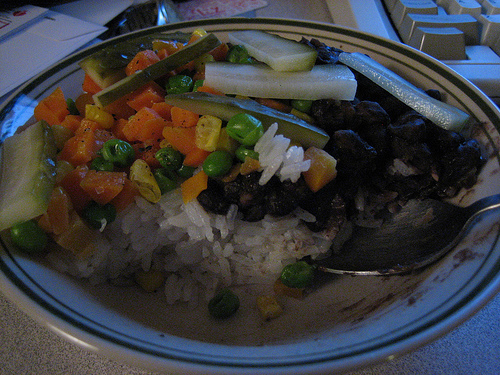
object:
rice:
[257, 155, 284, 186]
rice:
[219, 242, 237, 260]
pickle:
[90, 35, 228, 112]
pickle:
[163, 90, 331, 153]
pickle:
[79, 31, 190, 90]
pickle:
[2, 118, 59, 229]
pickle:
[218, 28, 324, 72]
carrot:
[122, 106, 169, 142]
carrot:
[163, 126, 197, 153]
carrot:
[34, 86, 70, 125]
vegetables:
[9, 37, 399, 210]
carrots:
[80, 170, 124, 206]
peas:
[235, 146, 258, 162]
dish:
[4, 17, 494, 365]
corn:
[192, 115, 222, 152]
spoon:
[303, 189, 499, 279]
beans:
[202, 151, 233, 178]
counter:
[2, 1, 500, 371]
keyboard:
[332, 1, 498, 85]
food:
[4, 27, 479, 311]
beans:
[225, 111, 264, 146]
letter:
[2, 3, 102, 86]